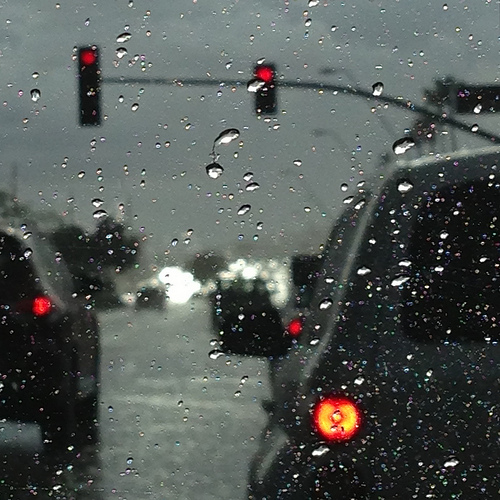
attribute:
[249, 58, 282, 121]
traffic light — red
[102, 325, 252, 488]
street — wet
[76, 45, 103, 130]
traffic light — ahead, black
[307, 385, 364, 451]
taillights — lit, red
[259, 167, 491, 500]
car — stopped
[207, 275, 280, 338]
car — stopped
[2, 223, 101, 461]
car — stopped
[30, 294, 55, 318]
lights — red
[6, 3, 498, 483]
scene — rainy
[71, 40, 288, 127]
lights — tall, lit, red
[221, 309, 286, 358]
side mirror — small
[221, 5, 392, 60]
sky — dark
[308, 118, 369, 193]
modern street lights — off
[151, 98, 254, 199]
rainy sky — cloudy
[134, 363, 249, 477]
road — gray